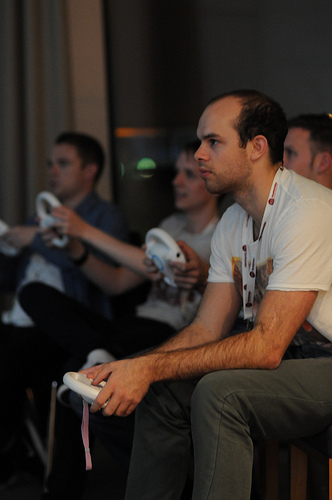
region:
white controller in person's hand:
[36, 187, 73, 244]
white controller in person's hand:
[61, 369, 118, 413]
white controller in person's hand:
[144, 229, 192, 288]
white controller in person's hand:
[4, 218, 19, 264]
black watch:
[67, 248, 92, 269]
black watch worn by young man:
[70, 250, 89, 267]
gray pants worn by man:
[210, 377, 324, 415]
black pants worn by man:
[33, 305, 92, 343]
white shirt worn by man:
[283, 194, 318, 266]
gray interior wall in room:
[130, 15, 296, 80]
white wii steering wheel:
[34, 189, 71, 248]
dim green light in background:
[136, 154, 156, 178]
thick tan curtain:
[3, 0, 108, 208]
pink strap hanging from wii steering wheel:
[78, 399, 95, 472]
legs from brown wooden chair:
[261, 438, 329, 498]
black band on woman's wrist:
[67, 247, 89, 268]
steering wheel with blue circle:
[143, 225, 186, 290]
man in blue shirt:
[3, 128, 126, 328]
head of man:
[282, 109, 329, 189]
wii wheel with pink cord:
[60, 368, 112, 407]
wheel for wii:
[57, 359, 127, 432]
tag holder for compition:
[230, 225, 271, 333]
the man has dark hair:
[174, 96, 298, 217]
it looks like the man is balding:
[182, 87, 283, 211]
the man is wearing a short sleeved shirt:
[186, 208, 329, 292]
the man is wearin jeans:
[201, 371, 310, 498]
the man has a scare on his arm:
[249, 302, 301, 345]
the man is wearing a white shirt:
[195, 192, 323, 295]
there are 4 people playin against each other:
[17, 122, 328, 257]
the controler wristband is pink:
[77, 397, 99, 482]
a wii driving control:
[46, 357, 128, 425]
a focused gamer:
[180, 89, 331, 364]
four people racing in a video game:
[37, 114, 329, 263]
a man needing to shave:
[189, 84, 290, 190]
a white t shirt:
[209, 194, 331, 335]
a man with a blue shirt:
[40, 130, 123, 324]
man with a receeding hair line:
[178, 76, 287, 203]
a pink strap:
[75, 401, 113, 468]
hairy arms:
[137, 345, 284, 380]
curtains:
[2, 5, 134, 243]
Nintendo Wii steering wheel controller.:
[53, 368, 124, 472]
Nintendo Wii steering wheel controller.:
[142, 227, 188, 288]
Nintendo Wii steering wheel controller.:
[36, 191, 71, 248]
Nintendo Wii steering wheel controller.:
[0, 218, 17, 259]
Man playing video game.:
[57, 86, 330, 498]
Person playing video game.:
[13, 137, 225, 450]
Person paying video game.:
[0, 129, 129, 345]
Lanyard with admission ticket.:
[239, 162, 286, 335]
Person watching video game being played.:
[278, 110, 330, 195]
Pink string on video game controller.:
[80, 395, 90, 472]